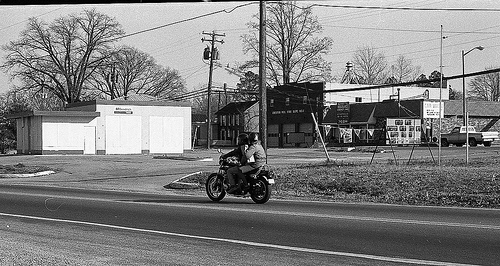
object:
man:
[221, 133, 250, 192]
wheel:
[248, 176, 273, 204]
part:
[257, 190, 267, 198]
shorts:
[239, 161, 255, 173]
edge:
[173, 190, 484, 209]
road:
[0, 181, 480, 263]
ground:
[1, 143, 499, 266]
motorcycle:
[204, 143, 275, 203]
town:
[1, 0, 500, 266]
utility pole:
[198, 31, 225, 149]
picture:
[1, 1, 500, 266]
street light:
[460, 43, 483, 165]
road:
[11, 144, 484, 195]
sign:
[385, 118, 423, 146]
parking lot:
[0, 136, 390, 193]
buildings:
[213, 99, 261, 145]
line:
[1, 191, 500, 230]